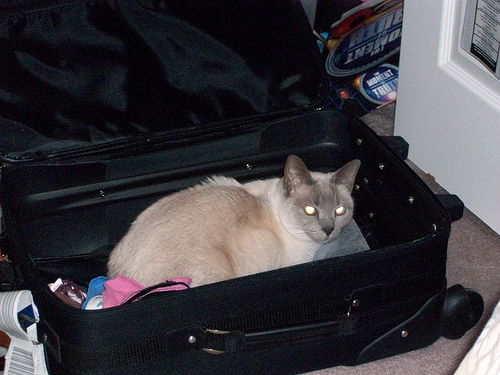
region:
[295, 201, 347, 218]
Glare in the cat eyes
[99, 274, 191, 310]
Pink pair of panties.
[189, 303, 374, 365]
Handle for a bag.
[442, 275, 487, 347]
Wheel for the luggage.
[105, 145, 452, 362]
A cat in a bag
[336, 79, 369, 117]
A man on a box.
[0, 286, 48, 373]
Tag on the luggage.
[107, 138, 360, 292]
A white cat.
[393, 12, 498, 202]
The door by the bag.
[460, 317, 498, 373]
The matress in the corner.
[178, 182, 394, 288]
this is a cat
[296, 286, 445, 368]
this is a bag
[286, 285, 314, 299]
the bag is black in color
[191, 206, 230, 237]
thew cat is white in color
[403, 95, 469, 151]
this is the wall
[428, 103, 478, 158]
the wall is white in color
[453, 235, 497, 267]
this is the floor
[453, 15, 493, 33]
this is the window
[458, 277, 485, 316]
this is a wheel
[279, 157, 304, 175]
this is the ear of the cat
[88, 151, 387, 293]
light is reflecting in the cat's eyes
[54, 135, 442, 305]
a cat is in a suitcase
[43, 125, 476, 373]
a cat is in a black suitcase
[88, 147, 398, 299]
the cat is beige in color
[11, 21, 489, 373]
the suitcase is open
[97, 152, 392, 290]
the cat is looking at the camera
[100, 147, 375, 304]
the cat is awake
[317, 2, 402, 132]
a board game is on the floor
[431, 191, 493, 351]
the suitcase has wheels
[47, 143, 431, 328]
clothing is in the suitcase underneath the cat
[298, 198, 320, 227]
Left eye on cat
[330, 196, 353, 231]
Right eye on cat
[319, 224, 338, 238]
Cat's nose is Black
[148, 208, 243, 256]
Cat's fur is light brown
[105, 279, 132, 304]
Pink panties in suitcase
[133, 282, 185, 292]
Black lining on panties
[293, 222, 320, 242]
Cat's whiskers are grey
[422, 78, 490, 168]
White paint on door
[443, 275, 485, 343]
Black wheel on carry on bag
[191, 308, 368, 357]
Black handle on carry on bag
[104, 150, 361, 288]
tan and grey cat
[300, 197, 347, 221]
glowing eyes of cat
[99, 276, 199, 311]
pink article of clothing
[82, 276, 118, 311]
blue and white article of clothing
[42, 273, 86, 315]
brown and white article of clothing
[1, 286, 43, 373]
airport ID sticker on suitcase handle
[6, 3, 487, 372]
black rolling suitcase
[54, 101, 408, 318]
cat sitting in suitcase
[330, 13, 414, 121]
box of game called "Moment of Truth"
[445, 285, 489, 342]
wheel on rolling suitcase